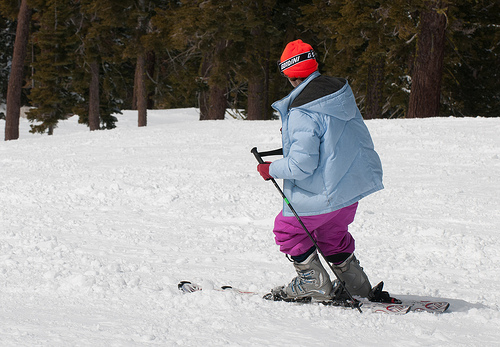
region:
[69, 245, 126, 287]
chunks of snow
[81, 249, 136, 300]
the snow is white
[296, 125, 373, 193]
the blue jacket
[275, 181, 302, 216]
a ski pole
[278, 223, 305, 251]
purple sweats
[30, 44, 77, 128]
a tree that is green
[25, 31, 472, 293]
this is a ski area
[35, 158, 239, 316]
the snow is deep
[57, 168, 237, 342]
the snow is rough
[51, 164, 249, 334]
the snow is bright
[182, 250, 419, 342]
these are skis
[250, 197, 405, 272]
the skis are pink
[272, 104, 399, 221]
the jacket is puffy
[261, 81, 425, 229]
the jacket is light blue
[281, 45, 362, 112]
the beanie is neon color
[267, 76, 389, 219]
woman wearing powder blue coat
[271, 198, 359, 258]
woman wearing magenta ski pants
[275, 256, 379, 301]
woman wearing silver ski boots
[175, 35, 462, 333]
woman skiing on mountain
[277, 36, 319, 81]
woman wearing red and black ski hat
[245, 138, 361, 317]
woman holding black ski pole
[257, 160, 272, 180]
red cold weather glove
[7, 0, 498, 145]
green pine trees lining slope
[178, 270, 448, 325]
red skis buried in snow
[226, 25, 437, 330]
person is skiing on the snow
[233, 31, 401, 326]
person wearing blue coat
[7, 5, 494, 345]
a forest on side snow trail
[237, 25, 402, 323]
person with winter pant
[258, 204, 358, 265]
pant is color pink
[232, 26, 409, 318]
woman holding a black pole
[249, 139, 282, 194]
handle of pole is black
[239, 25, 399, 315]
woman is bent on her knees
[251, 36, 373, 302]
skier wearing a orange hat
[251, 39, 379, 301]
skier wearing pink snow pants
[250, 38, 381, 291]
skier holding black ski poles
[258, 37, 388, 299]
skier looking at tall green trees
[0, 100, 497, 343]
ground covered in soft white snow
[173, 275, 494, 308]
long skis embedded in snow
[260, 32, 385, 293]
skier wearing pink gloves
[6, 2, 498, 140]
tall green trees in background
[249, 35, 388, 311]
skier in purple pants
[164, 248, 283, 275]
tracks in the snow from skies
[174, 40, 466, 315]
person skiing in snow cloths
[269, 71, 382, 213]
powder bue ski jacket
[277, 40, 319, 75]
orange ski cap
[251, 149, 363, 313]
someone's left ski pole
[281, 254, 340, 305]
a left ski boot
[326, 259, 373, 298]
a right ski boot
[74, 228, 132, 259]
snow on the ground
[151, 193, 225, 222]
tracks on the snow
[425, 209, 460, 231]
the snow is white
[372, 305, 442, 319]
skis on the snow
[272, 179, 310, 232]
pole in the hand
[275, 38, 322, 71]
the hat is red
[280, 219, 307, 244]
the pants are purple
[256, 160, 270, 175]
the glove is red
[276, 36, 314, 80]
A person is wearing a red hat.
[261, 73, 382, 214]
A jacket is blue.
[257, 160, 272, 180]
A person is wearing red gloves.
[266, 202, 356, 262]
The person is wearing a purple pants.